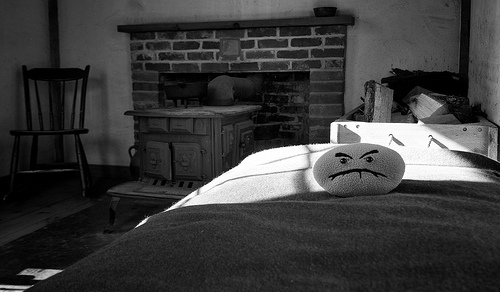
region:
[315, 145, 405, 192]
A pillow on the bed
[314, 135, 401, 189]
The pillow has a face design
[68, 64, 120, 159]
A shadow on the wall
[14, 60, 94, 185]
A wooden chair by the wall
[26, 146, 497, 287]
A bed near the fireplace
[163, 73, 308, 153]
A fireplace in the room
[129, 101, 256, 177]
A cabinet in front of the fireplace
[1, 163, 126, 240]
The ground below the chair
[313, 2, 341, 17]
A bowl above the fireplace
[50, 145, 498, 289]
Sheets on the bed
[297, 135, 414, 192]
frowny face pillow on bed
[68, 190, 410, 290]
black furry blanket on bed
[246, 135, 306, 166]
white sheet at top of bed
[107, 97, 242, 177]
brown wooden dresser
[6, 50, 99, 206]
brown chair in corner of room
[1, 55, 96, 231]
wooden chair in corner of room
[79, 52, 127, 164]
shadow of chair on wall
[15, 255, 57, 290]
sun light hitting the floor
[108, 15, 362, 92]
brick fireplace in the room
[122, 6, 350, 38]
wooden mantle on top of fire place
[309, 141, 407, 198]
Frowning pillow on top of bed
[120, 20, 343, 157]
Brick fireplace in background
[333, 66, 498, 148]
Firewood at the foot of the bed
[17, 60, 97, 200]
Wooden chair in the corner of the room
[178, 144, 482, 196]
Sunlight hitting bed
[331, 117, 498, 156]
Sunlight hitting box holding the firewood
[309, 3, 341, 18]
Bowl on top of the fireplace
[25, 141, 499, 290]
Wool sheets on bed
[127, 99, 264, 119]
Ashes on top of wood burner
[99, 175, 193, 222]
Table holding wood burner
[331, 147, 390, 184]
A grumpy face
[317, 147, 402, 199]
A grumpy face on the pillow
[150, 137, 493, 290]
A pillow on the bed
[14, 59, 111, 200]
A wooden chair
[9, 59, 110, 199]
A chair in the corner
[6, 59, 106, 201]
An empty brown chair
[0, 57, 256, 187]
A wooden stove by the chair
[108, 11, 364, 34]
A large mantle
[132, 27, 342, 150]
A brick fireplace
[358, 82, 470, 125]
A stack of firewood in the corner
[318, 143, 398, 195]
the pillow has a face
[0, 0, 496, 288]
the photo is black and white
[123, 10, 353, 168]
the fire place is made of brick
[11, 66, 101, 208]
a chair in the corner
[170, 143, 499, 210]
the sunlight shines in bed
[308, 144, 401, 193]
the pillow has an angry face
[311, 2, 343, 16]
a dish on fire place mantel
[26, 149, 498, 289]
the bed has dark sheets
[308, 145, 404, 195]
the pillow is circle shape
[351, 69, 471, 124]
the logs are in the corner